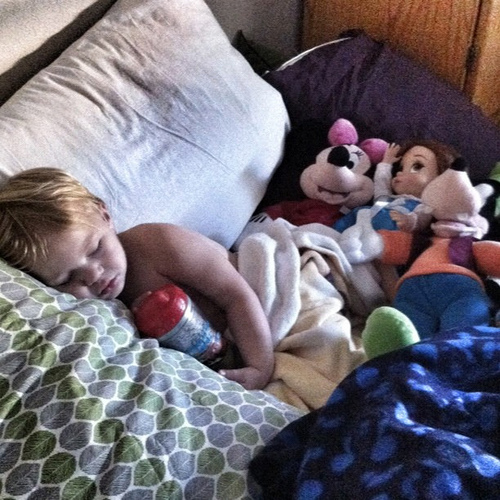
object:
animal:
[362, 157, 499, 360]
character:
[330, 141, 462, 305]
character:
[361, 158, 500, 361]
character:
[233, 118, 387, 251]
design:
[2, 350, 150, 497]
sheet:
[245, 318, 499, 500]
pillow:
[0, 260, 307, 499]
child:
[0, 167, 274, 391]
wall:
[415, 1, 462, 50]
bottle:
[134, 283, 225, 363]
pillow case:
[0, 263, 312, 499]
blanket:
[247, 325, 499, 498]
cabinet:
[302, 1, 500, 127]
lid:
[133, 284, 188, 338]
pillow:
[264, 31, 500, 186]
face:
[30, 224, 127, 299]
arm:
[157, 232, 274, 366]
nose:
[76, 258, 104, 286]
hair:
[0, 167, 105, 272]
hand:
[218, 366, 266, 390]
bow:
[328, 118, 388, 164]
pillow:
[0, 1, 290, 251]